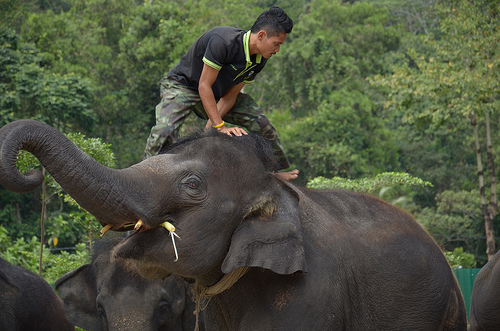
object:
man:
[144, 5, 312, 182]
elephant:
[0, 117, 473, 330]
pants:
[143, 71, 293, 172]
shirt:
[166, 25, 268, 98]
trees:
[484, 2, 500, 102]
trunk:
[0, 116, 168, 232]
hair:
[249, 5, 296, 40]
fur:
[179, 126, 216, 151]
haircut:
[270, 5, 289, 24]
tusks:
[132, 218, 145, 230]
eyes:
[181, 174, 205, 190]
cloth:
[183, 265, 252, 330]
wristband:
[211, 120, 225, 128]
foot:
[267, 168, 300, 182]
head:
[249, 3, 295, 59]